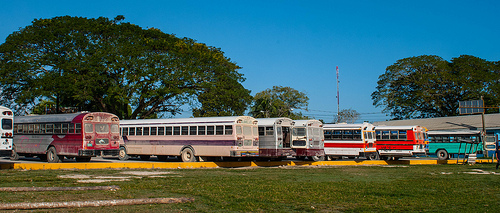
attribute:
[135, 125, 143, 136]
window — square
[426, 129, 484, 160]
bus — turquoise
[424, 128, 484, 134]
top — gray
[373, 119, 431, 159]
bus — white, red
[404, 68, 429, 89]
leaves — green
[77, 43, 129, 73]
leaves — green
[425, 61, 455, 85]
leaves — green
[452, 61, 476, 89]
leaves — green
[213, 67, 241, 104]
leaves — green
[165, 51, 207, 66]
leaves — green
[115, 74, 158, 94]
leaves — green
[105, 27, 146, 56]
leaves — green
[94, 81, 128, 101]
leaves — green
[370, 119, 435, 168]
bus — bright red, white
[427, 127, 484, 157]
one — green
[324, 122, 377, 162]
bus — white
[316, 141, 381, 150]
stripe — red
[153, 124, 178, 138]
window — square shaped